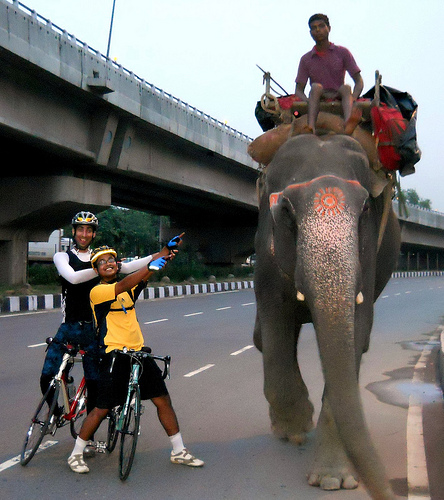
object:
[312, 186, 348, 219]
disk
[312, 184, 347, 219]
small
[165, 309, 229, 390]
portion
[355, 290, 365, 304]
tusk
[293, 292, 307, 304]
large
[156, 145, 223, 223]
portion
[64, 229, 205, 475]
man's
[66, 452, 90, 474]
sneakers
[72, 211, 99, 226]
helmet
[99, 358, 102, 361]
bottle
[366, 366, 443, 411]
spot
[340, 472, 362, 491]
toes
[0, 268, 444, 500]
road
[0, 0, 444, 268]
overpass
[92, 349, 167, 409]
shorts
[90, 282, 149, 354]
shirt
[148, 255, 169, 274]
gloves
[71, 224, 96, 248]
faces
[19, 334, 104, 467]
bicycle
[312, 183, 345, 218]
marking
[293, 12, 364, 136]
man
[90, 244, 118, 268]
helmet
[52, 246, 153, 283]
shirt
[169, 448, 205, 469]
shoes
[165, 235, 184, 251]
gloves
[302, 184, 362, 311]
face paint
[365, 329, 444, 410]
puddles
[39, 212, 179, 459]
boy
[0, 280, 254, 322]
curb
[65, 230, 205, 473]
boy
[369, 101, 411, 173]
back pack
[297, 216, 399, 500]
elephant trunk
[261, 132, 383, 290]
head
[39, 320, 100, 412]
pants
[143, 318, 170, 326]
dividers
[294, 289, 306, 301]
tusk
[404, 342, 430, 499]
line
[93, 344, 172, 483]
bicycle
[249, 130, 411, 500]
elephant